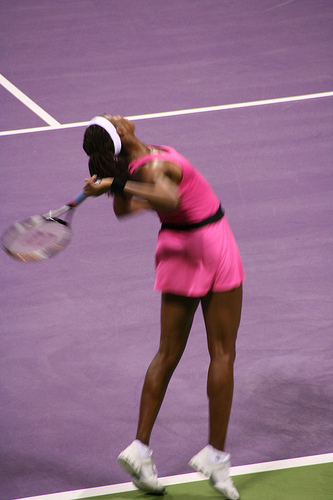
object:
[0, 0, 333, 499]
tennis court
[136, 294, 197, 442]
leg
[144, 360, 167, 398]
calf muscle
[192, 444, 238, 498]
feet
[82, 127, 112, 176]
hair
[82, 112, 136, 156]
head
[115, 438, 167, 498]
shoe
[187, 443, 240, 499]
shoe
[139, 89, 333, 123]
white line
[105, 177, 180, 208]
arm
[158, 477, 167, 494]
top toes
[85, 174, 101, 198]
grip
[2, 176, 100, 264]
racquet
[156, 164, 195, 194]
tank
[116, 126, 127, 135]
ear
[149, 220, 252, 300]
skirt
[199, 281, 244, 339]
thigh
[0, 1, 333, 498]
surface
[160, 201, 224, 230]
belt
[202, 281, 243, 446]
leg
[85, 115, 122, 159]
headband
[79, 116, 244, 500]
player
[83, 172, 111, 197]
hand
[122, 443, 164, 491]
foot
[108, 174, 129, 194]
wristband